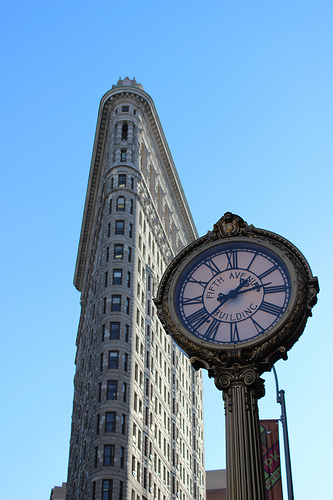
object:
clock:
[162, 231, 293, 350]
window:
[110, 266, 124, 286]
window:
[102, 409, 116, 433]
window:
[103, 443, 115, 468]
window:
[106, 377, 119, 403]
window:
[107, 316, 120, 340]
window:
[114, 193, 127, 213]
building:
[60, 71, 207, 499]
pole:
[222, 374, 265, 499]